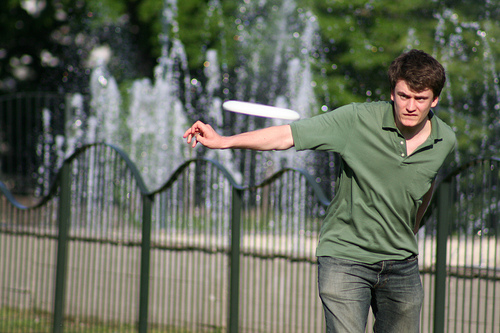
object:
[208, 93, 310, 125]
frisbee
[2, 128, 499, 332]
fence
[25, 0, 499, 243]
fountain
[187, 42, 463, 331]
man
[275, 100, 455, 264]
shirt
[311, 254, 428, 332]
jeans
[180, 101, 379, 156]
arms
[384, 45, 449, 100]
hair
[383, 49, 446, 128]
head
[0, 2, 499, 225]
trees